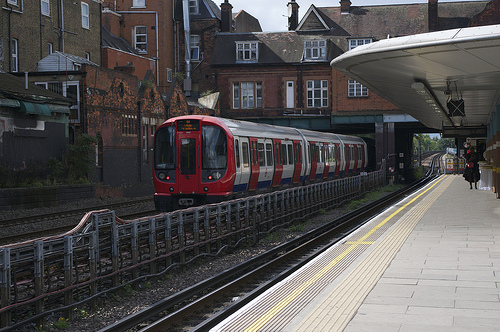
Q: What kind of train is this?
A: Subway.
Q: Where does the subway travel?
A: Underground.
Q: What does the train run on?
A: Tracks.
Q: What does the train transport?
A: Passengers.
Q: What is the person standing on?
A: Platform.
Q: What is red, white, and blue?
A: Train.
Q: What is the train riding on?
A: Rails.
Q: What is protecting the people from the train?
A: Guard Rail.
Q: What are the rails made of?
A: Metal.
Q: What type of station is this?
A: Train.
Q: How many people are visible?
A: One.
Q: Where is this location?
A: Train station.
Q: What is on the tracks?
A: A train.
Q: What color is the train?
A: Red and white.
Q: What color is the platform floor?
A: Beige.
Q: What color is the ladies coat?
A: Black.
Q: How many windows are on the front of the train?
A: Two.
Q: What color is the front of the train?
A: Red.